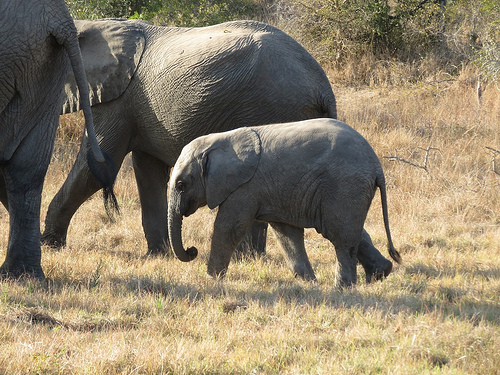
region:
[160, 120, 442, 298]
This is an elephant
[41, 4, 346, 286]
This is an elephant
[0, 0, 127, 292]
This is an elephant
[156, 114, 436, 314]
This is an elephant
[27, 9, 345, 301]
This is an elephant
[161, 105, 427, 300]
This is an elephant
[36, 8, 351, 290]
This is an elephant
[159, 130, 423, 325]
This is an elephant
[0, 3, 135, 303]
This is an elephant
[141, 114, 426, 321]
This is an elephant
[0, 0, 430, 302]
rambling [jack] elephants. three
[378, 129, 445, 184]
a broken branch in the blond dry grass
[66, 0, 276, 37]
some greenery left, leaves of bush or low tree height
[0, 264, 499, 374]
a few small patches, even, of green grass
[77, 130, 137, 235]
an unusually brush long elephant tail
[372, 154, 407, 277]
a long long baby elephant's tail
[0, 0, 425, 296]
old-fashioned nuclear family, pachyderm style: the clever parents: a huge dad, a mid-size mom, accompany a baby elephant working to learn elephant ways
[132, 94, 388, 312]
this is a baby elephant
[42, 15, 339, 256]
this is an adult elephant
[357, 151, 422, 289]
grey tail on elephant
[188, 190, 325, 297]
front legs on elephant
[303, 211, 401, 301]
hind legs on elephant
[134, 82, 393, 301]
the elephant is dark grey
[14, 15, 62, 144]
wrinkles on elephant skin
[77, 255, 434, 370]
grass is green and yellow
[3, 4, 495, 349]
a baby elephant walking with its parents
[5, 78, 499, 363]
the grass appears brown and dead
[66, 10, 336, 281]
a larger eleohant is walking next to the baby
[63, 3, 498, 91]
There are bushes in the background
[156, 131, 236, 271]
a baby elephants head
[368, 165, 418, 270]
a baby elephants tail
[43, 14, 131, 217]
an adult elephants tail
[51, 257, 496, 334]
shadows on the dry grass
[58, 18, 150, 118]
an older elephants ear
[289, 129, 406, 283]
the rear end of a baby elephant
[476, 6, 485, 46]
green grass on the tree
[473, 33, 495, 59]
green grass on the tree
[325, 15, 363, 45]
green grass on the tree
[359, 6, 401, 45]
green grass on the tree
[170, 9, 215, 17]
green grass on the tree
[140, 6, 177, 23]
green grass on the tree